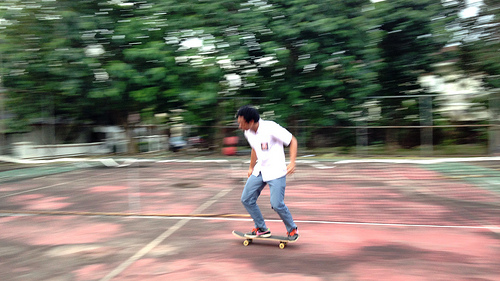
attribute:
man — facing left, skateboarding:
[231, 108, 298, 239]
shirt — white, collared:
[243, 117, 291, 184]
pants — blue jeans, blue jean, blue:
[241, 170, 297, 233]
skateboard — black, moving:
[233, 227, 299, 247]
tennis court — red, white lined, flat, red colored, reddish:
[1, 155, 500, 278]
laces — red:
[250, 227, 260, 234]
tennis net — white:
[2, 154, 500, 229]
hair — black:
[236, 105, 261, 125]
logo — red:
[261, 142, 270, 150]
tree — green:
[2, 2, 222, 137]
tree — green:
[220, 1, 499, 138]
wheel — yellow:
[242, 240, 251, 247]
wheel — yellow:
[278, 241, 285, 249]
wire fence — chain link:
[2, 85, 499, 161]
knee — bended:
[241, 197, 255, 208]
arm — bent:
[271, 122, 302, 163]